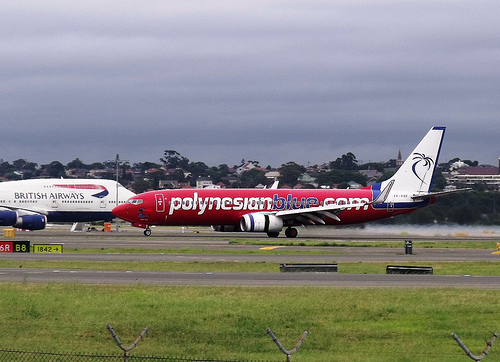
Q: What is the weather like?
A: It is cloudy.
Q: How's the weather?
A: It is cloudy.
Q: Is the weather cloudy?
A: Yes, it is cloudy.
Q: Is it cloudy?
A: Yes, it is cloudy.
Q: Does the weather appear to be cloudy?
A: Yes, it is cloudy.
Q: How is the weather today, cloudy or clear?
A: It is cloudy.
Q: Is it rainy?
A: No, it is cloudy.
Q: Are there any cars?
A: No, there are no cars.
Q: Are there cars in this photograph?
A: No, there are no cars.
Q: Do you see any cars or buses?
A: No, there are no cars or buses.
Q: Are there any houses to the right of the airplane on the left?
A: Yes, there is a house to the right of the plane.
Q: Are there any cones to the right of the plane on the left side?
A: No, there is a house to the right of the airplane.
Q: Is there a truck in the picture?
A: No, there are no trucks.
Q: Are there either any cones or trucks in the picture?
A: No, there are no trucks or cones.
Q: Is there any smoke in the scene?
A: Yes, there is smoke.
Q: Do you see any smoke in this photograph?
A: Yes, there is smoke.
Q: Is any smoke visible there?
A: Yes, there is smoke.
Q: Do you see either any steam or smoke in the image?
A: Yes, there is smoke.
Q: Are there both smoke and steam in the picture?
A: No, there is smoke but no steam.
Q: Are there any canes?
A: No, there are no canes.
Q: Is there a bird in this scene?
A: No, there are no birds.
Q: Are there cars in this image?
A: No, there are no cars.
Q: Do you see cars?
A: No, there are no cars.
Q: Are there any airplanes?
A: Yes, there is an airplane.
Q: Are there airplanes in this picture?
A: Yes, there is an airplane.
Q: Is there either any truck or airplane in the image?
A: Yes, there is an airplane.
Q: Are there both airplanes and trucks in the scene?
A: No, there is an airplane but no trucks.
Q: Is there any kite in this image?
A: No, there are no kites.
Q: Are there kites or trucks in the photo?
A: No, there are no kites or trucks.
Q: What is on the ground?
A: The plane is on the ground.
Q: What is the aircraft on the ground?
A: The aircraft is an airplane.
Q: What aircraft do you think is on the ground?
A: The aircraft is an airplane.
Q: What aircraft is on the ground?
A: The aircraft is an airplane.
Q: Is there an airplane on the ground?
A: Yes, there is an airplane on the ground.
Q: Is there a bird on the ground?
A: No, there is an airplane on the ground.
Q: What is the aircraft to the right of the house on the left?
A: The aircraft is an airplane.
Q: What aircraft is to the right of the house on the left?
A: The aircraft is an airplane.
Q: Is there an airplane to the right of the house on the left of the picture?
A: Yes, there is an airplane to the right of the house.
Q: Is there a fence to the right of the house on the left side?
A: No, there is an airplane to the right of the house.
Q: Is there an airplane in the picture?
A: Yes, there is an airplane.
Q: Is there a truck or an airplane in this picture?
A: Yes, there is an airplane.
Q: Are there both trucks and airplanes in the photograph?
A: No, there is an airplane but no trucks.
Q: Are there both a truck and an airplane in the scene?
A: No, there is an airplane but no trucks.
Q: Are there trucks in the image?
A: No, there are no trucks.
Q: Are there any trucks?
A: No, there are no trucks.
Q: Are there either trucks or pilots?
A: No, there are no trucks or pilots.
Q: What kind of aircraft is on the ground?
A: The aircraft is an airplane.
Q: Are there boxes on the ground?
A: No, there is an airplane on the ground.